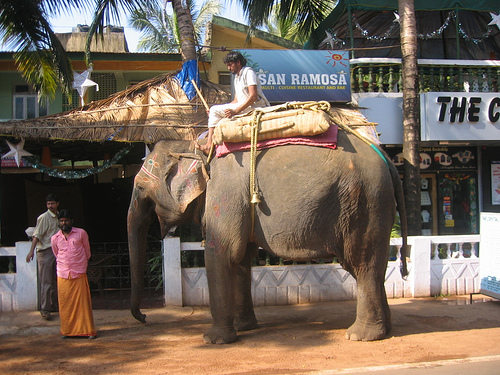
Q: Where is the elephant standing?
A: In front of store.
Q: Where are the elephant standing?
A: In front of building.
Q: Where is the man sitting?
A: Elephant.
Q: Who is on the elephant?
A: The man on the right.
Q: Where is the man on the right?
A: On the back of an elephant.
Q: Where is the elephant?
A: On the dirt.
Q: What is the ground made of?
A: Dirt.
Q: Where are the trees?
A: Behind the fence.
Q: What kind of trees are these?
A: Palm trees.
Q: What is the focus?
A: Elephant transportation.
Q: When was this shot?
A: Daytime.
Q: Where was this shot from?
A: Street.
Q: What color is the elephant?
A: Grey.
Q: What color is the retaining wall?
A: White.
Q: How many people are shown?
A: 3.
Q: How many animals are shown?
A: 1.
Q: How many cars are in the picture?
A: 0.